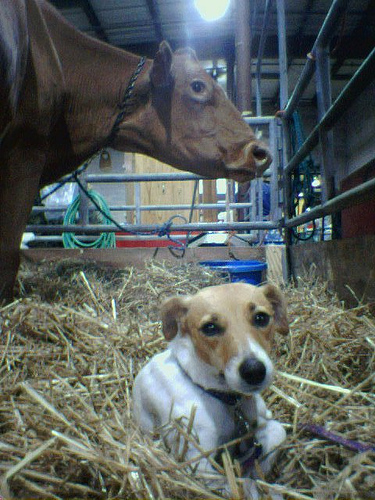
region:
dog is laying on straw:
[131, 278, 296, 479]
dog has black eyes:
[192, 301, 270, 339]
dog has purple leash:
[129, 277, 372, 472]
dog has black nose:
[237, 356, 269, 387]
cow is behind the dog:
[0, 4, 373, 497]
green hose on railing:
[60, 189, 117, 256]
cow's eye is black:
[187, 81, 208, 95]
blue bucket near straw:
[196, 252, 268, 286]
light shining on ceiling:
[189, 0, 232, 23]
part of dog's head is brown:
[160, 274, 292, 359]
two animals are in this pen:
[13, 10, 307, 496]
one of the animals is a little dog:
[119, 263, 302, 478]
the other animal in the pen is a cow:
[9, 8, 270, 220]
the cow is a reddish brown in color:
[4, 2, 270, 274]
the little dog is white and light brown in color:
[78, 252, 295, 489]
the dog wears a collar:
[167, 351, 245, 409]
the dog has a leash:
[219, 392, 374, 482]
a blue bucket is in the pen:
[195, 248, 277, 279]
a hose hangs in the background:
[60, 183, 114, 260]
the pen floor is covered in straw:
[14, 259, 367, 490]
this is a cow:
[17, 11, 291, 199]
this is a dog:
[135, 281, 314, 492]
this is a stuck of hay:
[44, 375, 106, 454]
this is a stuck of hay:
[36, 333, 105, 407]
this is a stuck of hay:
[304, 385, 367, 465]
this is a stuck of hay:
[97, 431, 176, 495]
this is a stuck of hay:
[21, 388, 106, 487]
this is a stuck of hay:
[76, 300, 128, 372]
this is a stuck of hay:
[284, 278, 350, 385]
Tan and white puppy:
[119, 267, 312, 484]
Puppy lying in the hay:
[0, 219, 372, 496]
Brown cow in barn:
[2, 1, 290, 312]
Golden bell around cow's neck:
[96, 46, 159, 184]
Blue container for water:
[186, 249, 276, 288]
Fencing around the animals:
[1, 133, 287, 235]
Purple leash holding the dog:
[229, 415, 372, 463]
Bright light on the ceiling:
[188, 4, 235, 21]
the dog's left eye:
[199, 309, 216, 335]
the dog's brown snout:
[239, 358, 268, 382]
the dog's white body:
[157, 370, 225, 436]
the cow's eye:
[190, 78, 207, 95]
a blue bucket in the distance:
[199, 257, 270, 284]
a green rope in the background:
[65, 203, 121, 249]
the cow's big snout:
[237, 138, 275, 172]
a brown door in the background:
[145, 185, 176, 205]